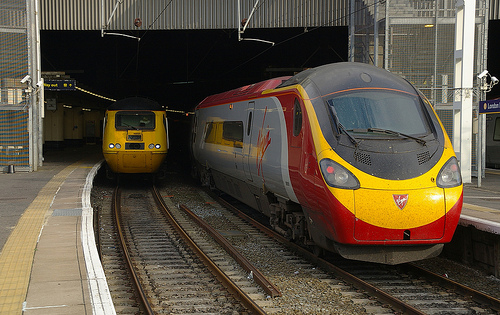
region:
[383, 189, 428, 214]
the red logo in the front of the train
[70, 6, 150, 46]
the stuff hanging from the wall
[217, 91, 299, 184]
virgin train ready to move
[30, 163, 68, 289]
the side of the train station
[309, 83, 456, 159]
the windows of the train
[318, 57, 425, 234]
the front of the train station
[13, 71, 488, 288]
a really nice train scene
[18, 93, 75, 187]
the entrance to the tunnell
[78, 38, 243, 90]
the train tunnell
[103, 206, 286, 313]
thebrow train tracks for the train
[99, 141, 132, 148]
Light on a train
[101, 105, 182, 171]
Front of a train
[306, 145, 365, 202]
Light on the front of a train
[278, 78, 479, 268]
Red and yellow train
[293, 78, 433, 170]
Window on a train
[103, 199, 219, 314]
Brown train track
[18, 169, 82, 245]
Brown and gray cement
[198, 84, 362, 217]
Gray, red and yellow train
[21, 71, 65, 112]
Cameras by a train station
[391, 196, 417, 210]
Emblem on the front of a train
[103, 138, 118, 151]
a light on a train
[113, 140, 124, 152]
a light on a train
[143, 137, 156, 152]
a light on a train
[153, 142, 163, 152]
a light on a train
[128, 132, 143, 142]
a light on a train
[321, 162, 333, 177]
a light on a train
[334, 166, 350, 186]
a light on a train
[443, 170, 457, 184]
a light on a train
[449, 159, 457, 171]
a light on a train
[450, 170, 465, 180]
a light on a train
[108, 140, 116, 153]
a light on a train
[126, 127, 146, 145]
a light on a train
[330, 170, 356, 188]
a light on a train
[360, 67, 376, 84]
a light on a train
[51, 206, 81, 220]
metal grate in stone paving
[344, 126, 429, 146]
windshield wipers on front window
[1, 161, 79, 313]
yellow tiled curbing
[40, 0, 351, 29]
corrugated metal sheeting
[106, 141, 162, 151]
two headlights are turned on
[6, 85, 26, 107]
lighted window in building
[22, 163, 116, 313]
stone paving with white painted curb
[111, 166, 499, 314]
side-by-side railway tracks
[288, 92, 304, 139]
circular window on side of vehicle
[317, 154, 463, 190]
two front headlamps